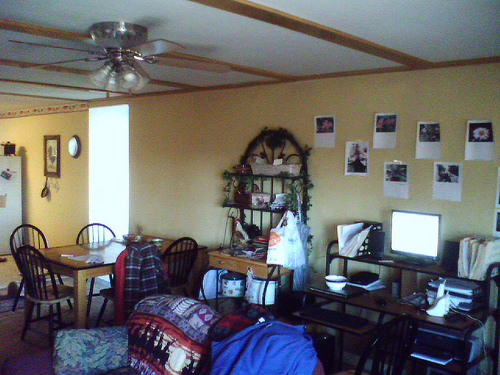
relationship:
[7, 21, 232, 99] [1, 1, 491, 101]
ceiling fan on roof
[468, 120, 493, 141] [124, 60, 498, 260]
picture on wall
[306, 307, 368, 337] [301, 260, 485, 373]
keyboard on desk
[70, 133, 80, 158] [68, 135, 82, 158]
black rim on clock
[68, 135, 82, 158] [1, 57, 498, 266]
clock on wall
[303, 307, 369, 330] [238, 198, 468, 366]
keyboard on desk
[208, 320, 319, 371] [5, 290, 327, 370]
garment draped over couch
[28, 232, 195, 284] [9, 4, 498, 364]
table in room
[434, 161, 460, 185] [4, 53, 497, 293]
picture on wall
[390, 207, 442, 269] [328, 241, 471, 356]
monitor on desk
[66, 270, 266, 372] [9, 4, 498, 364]
chair in room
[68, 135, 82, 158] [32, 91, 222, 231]
clock on wall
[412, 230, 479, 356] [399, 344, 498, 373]
printer on shelf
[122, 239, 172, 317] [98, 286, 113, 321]
clothes hanging on chair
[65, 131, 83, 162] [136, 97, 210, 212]
clock on wall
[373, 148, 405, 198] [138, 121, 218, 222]
picture on wall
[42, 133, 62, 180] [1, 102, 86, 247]
picture on wall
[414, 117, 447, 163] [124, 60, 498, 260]
picture on wall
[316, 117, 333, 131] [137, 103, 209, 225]
picture on wall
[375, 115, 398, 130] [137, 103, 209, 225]
picture on wall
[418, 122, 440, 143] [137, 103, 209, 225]
picture on wall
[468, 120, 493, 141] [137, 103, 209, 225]
picture on wall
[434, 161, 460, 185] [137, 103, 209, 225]
picture on wall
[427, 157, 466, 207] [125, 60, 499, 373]
picture on wall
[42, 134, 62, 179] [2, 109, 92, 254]
picture on wall